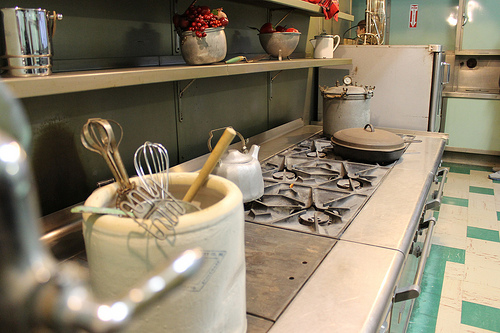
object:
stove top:
[326, 161, 372, 183]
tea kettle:
[205, 125, 264, 203]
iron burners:
[244, 133, 382, 229]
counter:
[59, 128, 443, 332]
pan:
[330, 124, 404, 164]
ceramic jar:
[79, 171, 246, 333]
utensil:
[78, 118, 131, 188]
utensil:
[122, 178, 187, 240]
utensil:
[180, 126, 237, 204]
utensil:
[133, 142, 169, 204]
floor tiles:
[414, 162, 499, 332]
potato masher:
[121, 141, 202, 218]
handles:
[390, 167, 446, 302]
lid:
[331, 124, 406, 153]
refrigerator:
[316, 45, 442, 132]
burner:
[235, 124, 414, 235]